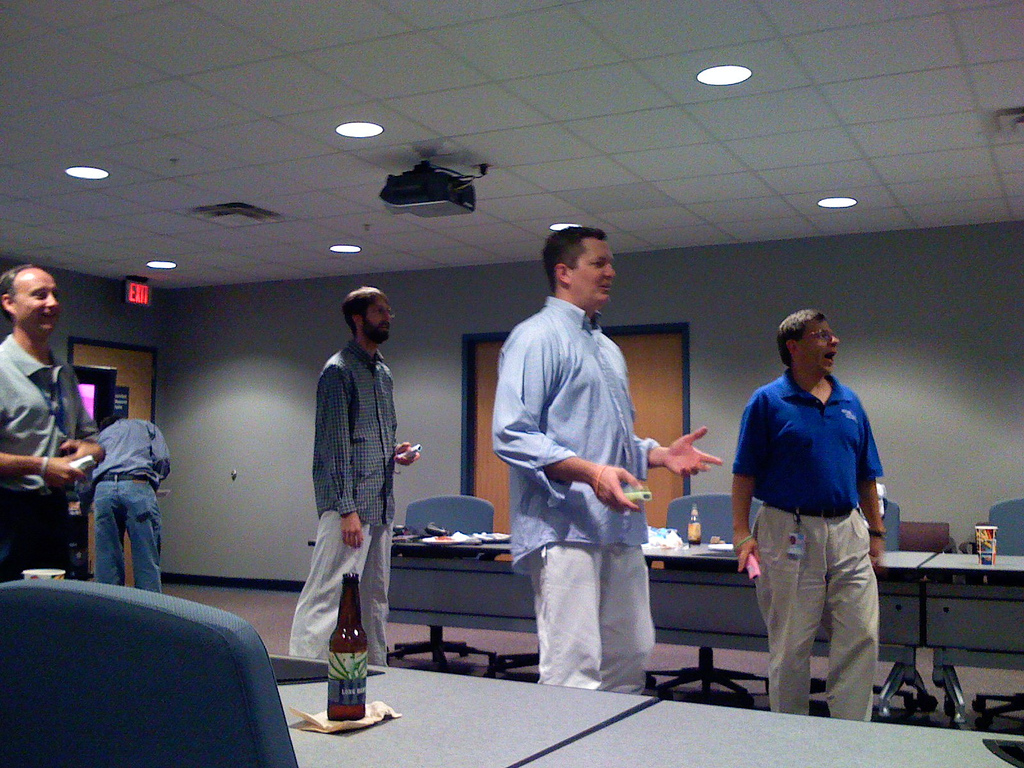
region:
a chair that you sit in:
[969, 495, 1019, 741]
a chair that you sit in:
[869, 484, 952, 721]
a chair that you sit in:
[649, 484, 773, 708]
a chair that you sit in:
[381, 472, 510, 651]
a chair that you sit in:
[13, 560, 320, 748]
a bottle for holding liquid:
[299, 555, 383, 724]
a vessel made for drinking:
[976, 516, 995, 567]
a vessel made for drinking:
[18, 569, 76, 590]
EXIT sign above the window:
[121, 275, 153, 308]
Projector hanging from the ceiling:
[368, 149, 496, 219]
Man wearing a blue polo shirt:
[732, 310, 892, 738]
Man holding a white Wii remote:
[491, 225, 723, 696]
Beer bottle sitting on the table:
[326, 569, 366, 718]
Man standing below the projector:
[288, 282, 422, 666]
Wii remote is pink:
[744, 544, 764, 583]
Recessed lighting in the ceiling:
[689, 66, 751, 87]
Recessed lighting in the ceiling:
[329, 114, 387, 141]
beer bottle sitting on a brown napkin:
[321, 572, 369, 718]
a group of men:
[17, 218, 975, 703]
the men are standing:
[11, 155, 961, 735]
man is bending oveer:
[54, 344, 209, 591]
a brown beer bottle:
[276, 534, 432, 743]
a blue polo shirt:
[718, 339, 900, 533]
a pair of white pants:
[512, 506, 672, 703]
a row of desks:
[337, 461, 1021, 702]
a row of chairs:
[393, 464, 1017, 592]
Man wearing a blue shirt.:
[729, 307, 892, 723]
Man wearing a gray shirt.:
[282, 284, 423, 670]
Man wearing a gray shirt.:
[0, 260, 106, 580]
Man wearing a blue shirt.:
[86, 411, 176, 596]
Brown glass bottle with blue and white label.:
[321, 568, 373, 727]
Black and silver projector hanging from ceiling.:
[373, 138, 494, 224]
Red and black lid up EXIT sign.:
[117, 275, 157, 310]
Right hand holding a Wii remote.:
[586, 459, 656, 513]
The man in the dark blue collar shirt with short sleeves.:
[729, 302, 904, 732]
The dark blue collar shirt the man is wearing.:
[733, 370, 885, 516]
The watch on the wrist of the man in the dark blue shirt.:
[865, 524, 889, 545]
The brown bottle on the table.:
[330, 563, 368, 713]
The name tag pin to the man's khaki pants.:
[785, 517, 804, 555]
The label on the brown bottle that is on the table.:
[324, 653, 367, 708]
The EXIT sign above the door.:
[119, 280, 157, 304]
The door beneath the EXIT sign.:
[74, 337, 158, 582]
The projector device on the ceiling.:
[382, 168, 485, 222]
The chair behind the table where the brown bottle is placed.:
[5, 565, 306, 765]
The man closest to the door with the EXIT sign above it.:
[88, 402, 184, 590]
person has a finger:
[684, 421, 710, 445]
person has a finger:
[699, 449, 725, 463]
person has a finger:
[614, 464, 640, 485]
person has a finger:
[611, 492, 640, 513]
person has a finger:
[354, 531, 365, 551]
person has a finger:
[672, 462, 686, 481]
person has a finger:
[678, 462, 695, 479]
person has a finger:
[687, 458, 704, 475]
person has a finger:
[735, 549, 748, 572]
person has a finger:
[871, 562, 876, 572]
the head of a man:
[517, 224, 634, 326]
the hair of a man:
[541, 239, 590, 274]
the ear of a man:
[544, 265, 587, 294]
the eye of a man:
[582, 256, 614, 270]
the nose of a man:
[593, 268, 633, 282]